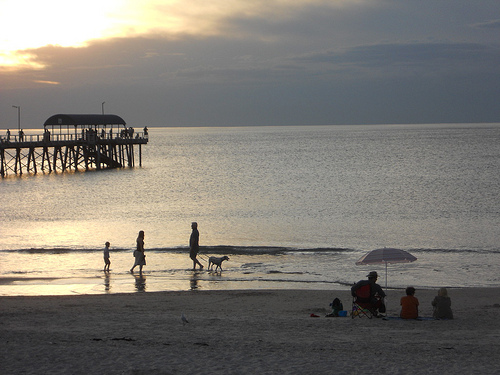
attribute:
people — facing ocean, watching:
[292, 260, 462, 329]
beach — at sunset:
[194, 309, 252, 369]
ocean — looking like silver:
[325, 160, 473, 212]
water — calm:
[158, 166, 223, 205]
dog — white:
[207, 254, 235, 282]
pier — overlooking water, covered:
[8, 105, 162, 180]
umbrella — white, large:
[354, 246, 428, 265]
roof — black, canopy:
[55, 114, 138, 126]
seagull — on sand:
[176, 307, 199, 330]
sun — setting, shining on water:
[33, 20, 135, 49]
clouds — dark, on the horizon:
[175, 7, 298, 67]